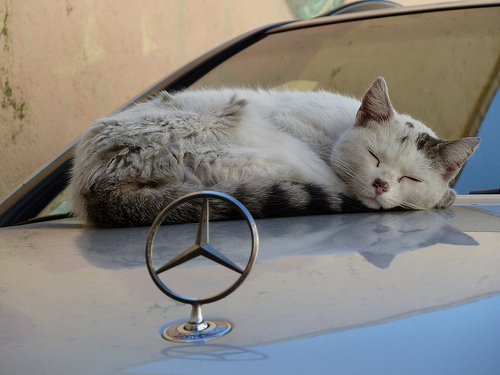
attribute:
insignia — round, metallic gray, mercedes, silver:
[144, 183, 281, 313]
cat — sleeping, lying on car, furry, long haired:
[87, 101, 470, 222]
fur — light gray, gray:
[159, 93, 247, 99]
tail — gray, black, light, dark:
[105, 185, 347, 223]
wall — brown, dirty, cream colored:
[52, 29, 153, 52]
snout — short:
[347, 173, 410, 217]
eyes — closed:
[373, 138, 425, 192]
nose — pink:
[372, 178, 391, 202]